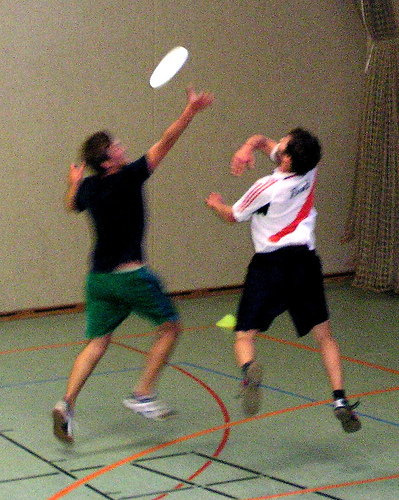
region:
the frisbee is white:
[150, 47, 188, 89]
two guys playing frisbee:
[50, 44, 359, 444]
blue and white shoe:
[124, 391, 175, 420]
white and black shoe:
[330, 399, 359, 432]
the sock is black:
[332, 387, 343, 397]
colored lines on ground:
[2, 322, 398, 499]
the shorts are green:
[84, 266, 177, 339]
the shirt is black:
[72, 154, 151, 270]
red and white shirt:
[233, 142, 317, 250]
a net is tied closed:
[343, 1, 398, 292]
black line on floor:
[190, 444, 255, 475]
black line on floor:
[263, 472, 302, 490]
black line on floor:
[312, 490, 339, 497]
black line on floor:
[202, 484, 237, 498]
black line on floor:
[130, 463, 197, 484]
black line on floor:
[203, 468, 262, 487]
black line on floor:
[114, 483, 190, 497]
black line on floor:
[69, 464, 96, 471]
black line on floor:
[134, 449, 186, 463]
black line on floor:
[1, 428, 78, 483]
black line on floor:
[83, 483, 112, 497]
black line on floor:
[5, 470, 59, 486]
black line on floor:
[50, 455, 69, 468]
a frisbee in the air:
[142, 33, 196, 94]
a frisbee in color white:
[142, 35, 196, 96]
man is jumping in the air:
[199, 119, 376, 440]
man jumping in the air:
[46, 81, 219, 456]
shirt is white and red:
[232, 162, 319, 253]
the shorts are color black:
[231, 244, 334, 338]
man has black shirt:
[37, 81, 213, 453]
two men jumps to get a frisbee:
[41, 35, 372, 457]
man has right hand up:
[42, 73, 217, 451]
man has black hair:
[202, 115, 337, 242]